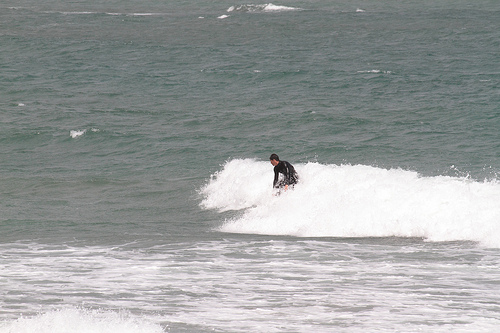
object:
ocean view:
[0, 0, 497, 333]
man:
[269, 154, 300, 196]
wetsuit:
[274, 161, 297, 188]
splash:
[0, 248, 500, 332]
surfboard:
[272, 185, 290, 196]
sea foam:
[3, 151, 498, 326]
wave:
[1, 159, 500, 333]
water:
[0, 0, 499, 333]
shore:
[0, 292, 499, 333]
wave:
[209, 0, 296, 19]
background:
[0, 0, 500, 333]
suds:
[0, 152, 499, 332]